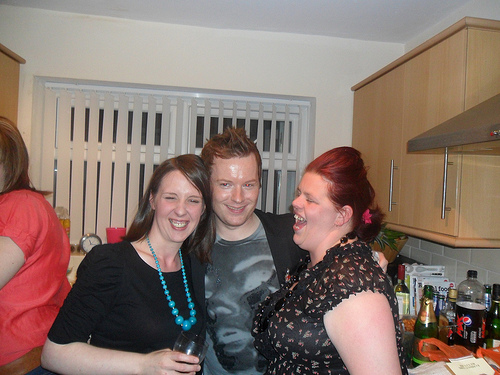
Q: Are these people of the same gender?
A: No, they are both male and female.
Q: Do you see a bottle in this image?
A: Yes, there is a bottle.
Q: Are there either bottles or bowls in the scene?
A: Yes, there is a bottle.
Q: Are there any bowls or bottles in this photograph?
A: Yes, there is a bottle.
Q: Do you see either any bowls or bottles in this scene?
A: Yes, there is a bottle.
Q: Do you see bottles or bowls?
A: Yes, there is a bottle.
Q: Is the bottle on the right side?
A: Yes, the bottle is on the right of the image.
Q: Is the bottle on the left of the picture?
A: No, the bottle is on the right of the image.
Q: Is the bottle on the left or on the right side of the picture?
A: The bottle is on the right of the image.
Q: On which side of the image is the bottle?
A: The bottle is on the right of the image.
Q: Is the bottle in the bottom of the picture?
A: Yes, the bottle is in the bottom of the image.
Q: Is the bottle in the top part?
A: No, the bottle is in the bottom of the image.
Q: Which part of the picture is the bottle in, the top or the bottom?
A: The bottle is in the bottom of the image.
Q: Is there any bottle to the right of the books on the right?
A: Yes, there is a bottle to the right of the books.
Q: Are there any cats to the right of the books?
A: No, there is a bottle to the right of the books.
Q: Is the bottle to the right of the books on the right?
A: Yes, the bottle is to the right of the books.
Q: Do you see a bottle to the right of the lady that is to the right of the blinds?
A: Yes, there is a bottle to the right of the lady.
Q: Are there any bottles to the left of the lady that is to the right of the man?
A: No, the bottle is to the right of the lady.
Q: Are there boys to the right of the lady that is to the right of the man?
A: No, there is a bottle to the right of the lady.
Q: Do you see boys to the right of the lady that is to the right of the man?
A: No, there is a bottle to the right of the lady.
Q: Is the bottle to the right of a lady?
A: Yes, the bottle is to the right of a lady.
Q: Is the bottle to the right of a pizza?
A: No, the bottle is to the right of a lady.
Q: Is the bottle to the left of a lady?
A: No, the bottle is to the right of a lady.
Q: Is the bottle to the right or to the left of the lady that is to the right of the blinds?
A: The bottle is to the right of the lady.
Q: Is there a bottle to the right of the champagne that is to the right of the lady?
A: Yes, there is a bottle to the right of the champagne.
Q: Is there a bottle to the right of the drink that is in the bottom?
A: Yes, there is a bottle to the right of the champagne.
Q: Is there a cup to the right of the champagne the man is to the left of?
A: No, there is a bottle to the right of the champagne.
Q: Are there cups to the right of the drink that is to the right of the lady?
A: No, there is a bottle to the right of the champagne.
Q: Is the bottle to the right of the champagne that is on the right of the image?
A: Yes, the bottle is to the right of the champagne.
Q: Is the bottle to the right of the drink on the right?
A: Yes, the bottle is to the right of the champagne.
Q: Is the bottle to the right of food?
A: No, the bottle is to the right of the champagne.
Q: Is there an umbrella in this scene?
A: No, there are no umbrellas.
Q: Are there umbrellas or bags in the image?
A: No, there are no umbrellas or bags.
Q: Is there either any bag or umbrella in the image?
A: No, there are no umbrellas or bags.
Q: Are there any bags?
A: No, there are no bags.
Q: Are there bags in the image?
A: No, there are no bags.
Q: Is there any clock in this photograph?
A: Yes, there is a clock.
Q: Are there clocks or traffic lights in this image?
A: Yes, there is a clock.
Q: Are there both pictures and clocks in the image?
A: No, there is a clock but no pictures.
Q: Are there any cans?
A: No, there are no cans.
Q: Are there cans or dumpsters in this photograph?
A: No, there are no cans or dumpsters.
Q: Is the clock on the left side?
A: Yes, the clock is on the left of the image.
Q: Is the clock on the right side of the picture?
A: No, the clock is on the left of the image.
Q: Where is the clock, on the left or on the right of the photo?
A: The clock is on the left of the image.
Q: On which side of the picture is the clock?
A: The clock is on the left of the image.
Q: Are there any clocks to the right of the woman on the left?
A: Yes, there is a clock to the right of the woman.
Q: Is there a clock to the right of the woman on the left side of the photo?
A: Yes, there is a clock to the right of the woman.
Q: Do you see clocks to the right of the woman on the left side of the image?
A: Yes, there is a clock to the right of the woman.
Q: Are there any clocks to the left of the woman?
A: No, the clock is to the right of the woman.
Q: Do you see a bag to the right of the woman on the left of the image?
A: No, there is a clock to the right of the woman.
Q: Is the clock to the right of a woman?
A: Yes, the clock is to the right of a woman.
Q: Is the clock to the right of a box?
A: No, the clock is to the right of a woman.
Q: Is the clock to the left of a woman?
A: No, the clock is to the right of a woman.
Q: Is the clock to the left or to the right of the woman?
A: The clock is to the right of the woman.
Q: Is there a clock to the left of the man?
A: Yes, there is a clock to the left of the man.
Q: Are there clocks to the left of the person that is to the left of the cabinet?
A: Yes, there is a clock to the left of the man.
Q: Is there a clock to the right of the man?
A: No, the clock is to the left of the man.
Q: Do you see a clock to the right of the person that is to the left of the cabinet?
A: No, the clock is to the left of the man.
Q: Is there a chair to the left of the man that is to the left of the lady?
A: No, there is a clock to the left of the man.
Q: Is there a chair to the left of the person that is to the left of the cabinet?
A: No, there is a clock to the left of the man.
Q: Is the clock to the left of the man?
A: Yes, the clock is to the left of the man.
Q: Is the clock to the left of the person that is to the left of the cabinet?
A: Yes, the clock is to the left of the man.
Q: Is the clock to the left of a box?
A: No, the clock is to the left of the man.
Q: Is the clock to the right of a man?
A: No, the clock is to the left of a man.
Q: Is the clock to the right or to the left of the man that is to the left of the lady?
A: The clock is to the left of the man.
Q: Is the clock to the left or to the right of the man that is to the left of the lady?
A: The clock is to the left of the man.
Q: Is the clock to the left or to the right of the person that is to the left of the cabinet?
A: The clock is to the left of the man.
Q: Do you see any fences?
A: No, there are no fences.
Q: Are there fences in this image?
A: No, there are no fences.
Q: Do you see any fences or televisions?
A: No, there are no fences or televisions.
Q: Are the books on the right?
A: Yes, the books are on the right of the image.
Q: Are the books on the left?
A: No, the books are on the right of the image.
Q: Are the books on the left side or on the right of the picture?
A: The books are on the right of the image.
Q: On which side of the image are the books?
A: The books are on the right of the image.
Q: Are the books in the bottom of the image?
A: Yes, the books are in the bottom of the image.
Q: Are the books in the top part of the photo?
A: No, the books are in the bottom of the image.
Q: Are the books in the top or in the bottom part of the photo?
A: The books are in the bottom of the image.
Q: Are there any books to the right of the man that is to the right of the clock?
A: Yes, there are books to the right of the man.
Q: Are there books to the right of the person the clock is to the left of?
A: Yes, there are books to the right of the man.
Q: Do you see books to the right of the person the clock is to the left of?
A: Yes, there are books to the right of the man.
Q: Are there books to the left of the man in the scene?
A: No, the books are to the right of the man.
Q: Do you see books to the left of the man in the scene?
A: No, the books are to the right of the man.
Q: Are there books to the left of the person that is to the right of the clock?
A: No, the books are to the right of the man.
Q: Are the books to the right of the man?
A: Yes, the books are to the right of the man.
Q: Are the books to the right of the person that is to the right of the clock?
A: Yes, the books are to the right of the man.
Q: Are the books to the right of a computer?
A: No, the books are to the right of the man.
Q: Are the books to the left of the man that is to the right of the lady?
A: No, the books are to the right of the man.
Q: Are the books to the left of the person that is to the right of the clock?
A: No, the books are to the right of the man.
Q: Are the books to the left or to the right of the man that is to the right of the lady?
A: The books are to the right of the man.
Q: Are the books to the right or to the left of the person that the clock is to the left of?
A: The books are to the right of the man.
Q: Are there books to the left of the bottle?
A: Yes, there are books to the left of the bottle.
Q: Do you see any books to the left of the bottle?
A: Yes, there are books to the left of the bottle.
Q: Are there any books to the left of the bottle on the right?
A: Yes, there are books to the left of the bottle.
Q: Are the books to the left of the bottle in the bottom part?
A: Yes, the books are to the left of the bottle.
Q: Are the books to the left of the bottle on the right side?
A: Yes, the books are to the left of the bottle.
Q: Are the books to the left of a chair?
A: No, the books are to the left of the bottle.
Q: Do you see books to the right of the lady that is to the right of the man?
A: Yes, there are books to the right of the lady.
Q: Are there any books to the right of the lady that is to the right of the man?
A: Yes, there are books to the right of the lady.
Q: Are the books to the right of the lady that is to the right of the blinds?
A: Yes, the books are to the right of the lady.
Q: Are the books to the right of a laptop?
A: No, the books are to the right of the lady.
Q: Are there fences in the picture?
A: No, there are no fences.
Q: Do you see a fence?
A: No, there are no fences.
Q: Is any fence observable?
A: No, there are no fences.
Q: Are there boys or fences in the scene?
A: No, there are no fences or boys.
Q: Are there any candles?
A: No, there are no candles.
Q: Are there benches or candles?
A: No, there are no candles or benches.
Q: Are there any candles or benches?
A: No, there are no candles or benches.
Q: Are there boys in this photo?
A: No, there are no boys.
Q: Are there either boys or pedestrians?
A: No, there are no boys or pedestrians.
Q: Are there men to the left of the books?
A: Yes, there is a man to the left of the books.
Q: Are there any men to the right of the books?
A: No, the man is to the left of the books.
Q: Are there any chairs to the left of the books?
A: No, there is a man to the left of the books.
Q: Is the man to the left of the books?
A: Yes, the man is to the left of the books.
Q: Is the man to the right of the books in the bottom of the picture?
A: No, the man is to the left of the books.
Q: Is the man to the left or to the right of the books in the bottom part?
A: The man is to the left of the books.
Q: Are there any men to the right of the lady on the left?
A: Yes, there is a man to the right of the lady.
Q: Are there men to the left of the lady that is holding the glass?
A: No, the man is to the right of the lady.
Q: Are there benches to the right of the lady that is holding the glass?
A: No, there is a man to the right of the lady.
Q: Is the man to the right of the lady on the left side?
A: Yes, the man is to the right of the lady.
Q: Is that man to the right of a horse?
A: No, the man is to the right of the lady.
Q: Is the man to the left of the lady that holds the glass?
A: No, the man is to the right of the lady.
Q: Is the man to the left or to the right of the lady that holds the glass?
A: The man is to the right of the lady.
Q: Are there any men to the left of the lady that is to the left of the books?
A: Yes, there is a man to the left of the lady.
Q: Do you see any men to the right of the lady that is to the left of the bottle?
A: No, the man is to the left of the lady.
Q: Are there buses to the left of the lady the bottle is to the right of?
A: No, there is a man to the left of the lady.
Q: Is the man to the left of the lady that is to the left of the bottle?
A: Yes, the man is to the left of the lady.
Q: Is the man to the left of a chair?
A: No, the man is to the left of the lady.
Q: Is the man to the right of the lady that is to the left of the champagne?
A: No, the man is to the left of the lady.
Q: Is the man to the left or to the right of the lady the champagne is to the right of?
A: The man is to the left of the lady.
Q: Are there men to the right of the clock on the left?
A: Yes, there is a man to the right of the clock.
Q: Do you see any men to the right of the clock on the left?
A: Yes, there is a man to the right of the clock.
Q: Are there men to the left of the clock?
A: No, the man is to the right of the clock.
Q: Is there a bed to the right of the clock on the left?
A: No, there is a man to the right of the clock.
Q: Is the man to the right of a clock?
A: Yes, the man is to the right of a clock.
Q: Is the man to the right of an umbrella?
A: No, the man is to the right of a clock.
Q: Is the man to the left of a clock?
A: No, the man is to the right of a clock.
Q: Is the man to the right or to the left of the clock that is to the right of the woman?
A: The man is to the right of the clock.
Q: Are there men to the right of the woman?
A: Yes, there is a man to the right of the woman.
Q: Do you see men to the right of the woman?
A: Yes, there is a man to the right of the woman.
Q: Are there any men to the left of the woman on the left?
A: No, the man is to the right of the woman.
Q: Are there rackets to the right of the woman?
A: No, there is a man to the right of the woman.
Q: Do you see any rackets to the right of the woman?
A: No, there is a man to the right of the woman.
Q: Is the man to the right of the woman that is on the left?
A: Yes, the man is to the right of the woman.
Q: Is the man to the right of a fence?
A: No, the man is to the right of the woman.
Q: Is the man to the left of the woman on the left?
A: No, the man is to the right of the woman.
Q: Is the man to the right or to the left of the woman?
A: The man is to the right of the woman.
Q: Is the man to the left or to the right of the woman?
A: The man is to the right of the woman.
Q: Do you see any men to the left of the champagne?
A: Yes, there is a man to the left of the champagne.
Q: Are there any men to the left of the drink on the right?
A: Yes, there is a man to the left of the champagne.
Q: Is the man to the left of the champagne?
A: Yes, the man is to the left of the champagne.